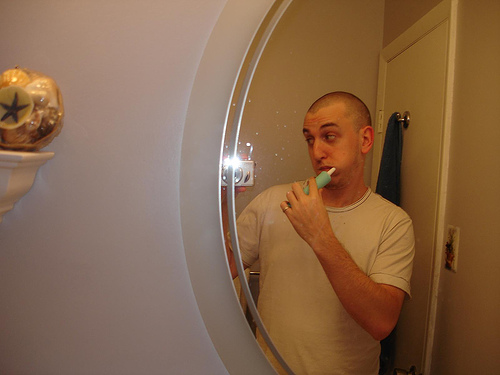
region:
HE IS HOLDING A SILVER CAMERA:
[221, 160, 253, 185]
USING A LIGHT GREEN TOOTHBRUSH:
[315, 172, 331, 187]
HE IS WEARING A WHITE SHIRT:
[235, 188, 412, 373]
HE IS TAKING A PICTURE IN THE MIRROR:
[179, 2, 498, 372]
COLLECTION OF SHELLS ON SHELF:
[0, 69, 62, 149]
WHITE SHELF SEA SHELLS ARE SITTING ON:
[1, 150, 51, 213]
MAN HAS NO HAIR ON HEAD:
[307, 90, 372, 125]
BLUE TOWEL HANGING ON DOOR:
[376, 115, 402, 209]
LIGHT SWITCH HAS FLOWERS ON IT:
[445, 225, 460, 274]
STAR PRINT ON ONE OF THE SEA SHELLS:
[1, 90, 28, 124]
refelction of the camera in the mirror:
[201, 154, 271, 189]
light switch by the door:
[438, 223, 463, 277]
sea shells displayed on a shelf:
[0, 61, 59, 212]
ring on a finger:
[276, 198, 297, 215]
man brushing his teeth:
[296, 90, 376, 202]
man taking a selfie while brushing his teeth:
[223, 87, 380, 222]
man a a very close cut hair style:
[300, 88, 379, 168]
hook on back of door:
[381, 106, 416, 136]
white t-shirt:
[238, 190, 410, 371]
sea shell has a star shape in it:
[0, 84, 34, 131]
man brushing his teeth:
[277, 82, 376, 244]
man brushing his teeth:
[260, 40, 385, 238]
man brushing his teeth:
[255, 66, 395, 251]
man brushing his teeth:
[284, 86, 382, 248]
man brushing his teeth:
[281, 71, 385, 281]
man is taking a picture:
[190, 70, 404, 262]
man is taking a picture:
[165, 48, 404, 300]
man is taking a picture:
[185, 82, 407, 253]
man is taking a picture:
[194, 83, 439, 303]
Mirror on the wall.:
[220, 0, 499, 374]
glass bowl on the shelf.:
[0, 64, 62, 151]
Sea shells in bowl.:
[0, 67, 64, 149]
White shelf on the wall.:
[1, 148, 58, 218]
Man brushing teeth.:
[219, 90, 412, 370]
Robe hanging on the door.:
[372, 102, 407, 357]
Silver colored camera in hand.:
[214, 142, 257, 193]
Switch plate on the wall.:
[440, 219, 465, 276]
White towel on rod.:
[229, 269, 260, 306]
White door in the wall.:
[373, 0, 450, 374]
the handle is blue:
[290, 169, 346, 198]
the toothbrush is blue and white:
[290, 166, 355, 196]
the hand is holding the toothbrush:
[273, 167, 340, 237]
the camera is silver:
[219, 148, 259, 192]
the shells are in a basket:
[1, 65, 67, 150]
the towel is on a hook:
[383, 104, 417, 204]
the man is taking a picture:
[231, 91, 411, 373]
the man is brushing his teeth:
[223, 92, 418, 372]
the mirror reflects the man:
[219, 38, 493, 369]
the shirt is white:
[232, 179, 416, 374]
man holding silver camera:
[217, 90, 417, 373]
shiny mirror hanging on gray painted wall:
[2, 2, 498, 372]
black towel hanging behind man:
[219, 90, 416, 372]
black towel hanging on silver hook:
[373, 109, 412, 373]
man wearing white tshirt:
[221, 91, 414, 373]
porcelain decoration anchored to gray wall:
[0, 0, 274, 372]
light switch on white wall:
[384, 0, 499, 373]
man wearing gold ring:
[220, 89, 417, 373]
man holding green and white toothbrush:
[218, 91, 414, 373]